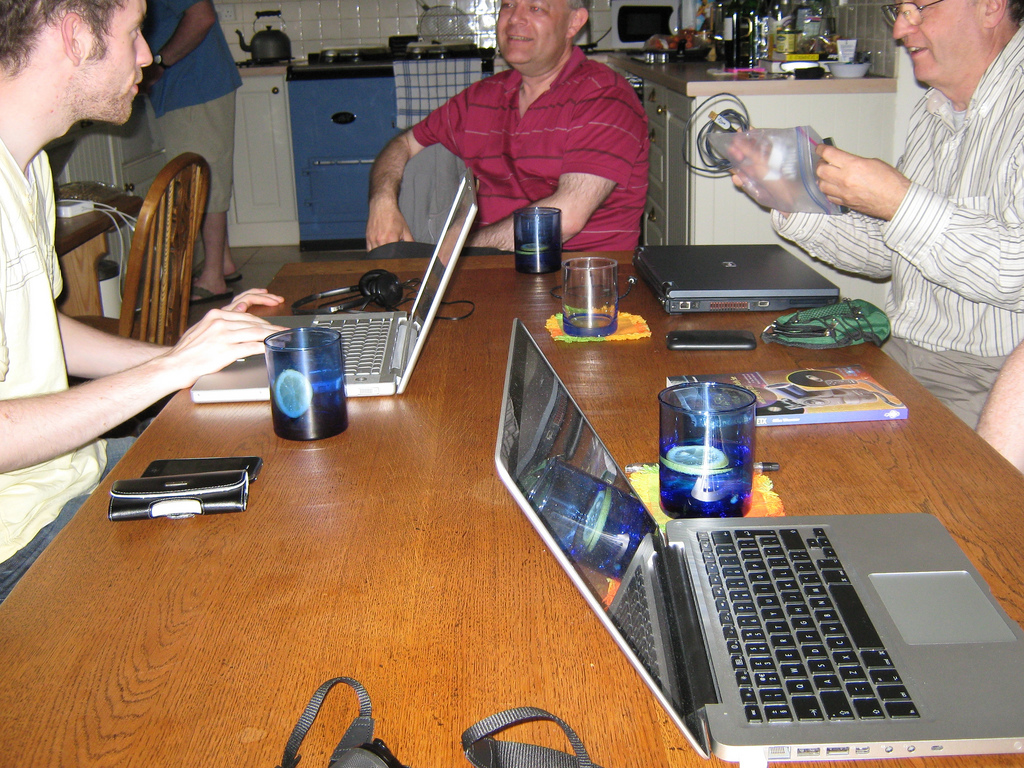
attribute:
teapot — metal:
[227, 13, 305, 77]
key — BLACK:
[762, 685, 782, 702]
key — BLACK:
[889, 699, 921, 719]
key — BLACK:
[820, 688, 855, 721]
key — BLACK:
[791, 694, 823, 724]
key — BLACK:
[781, 528, 808, 552]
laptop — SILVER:
[637, 245, 838, 316]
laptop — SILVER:
[191, 170, 480, 406]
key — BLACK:
[750, 656, 771, 670]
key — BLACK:
[748, 641, 774, 654]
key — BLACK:
[743, 625, 767, 642]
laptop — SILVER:
[492, 318, 1020, 761]